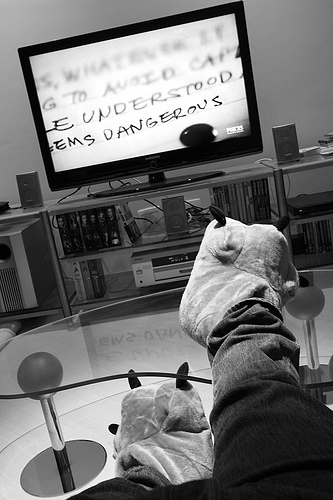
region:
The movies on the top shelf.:
[47, 213, 123, 247]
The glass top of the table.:
[6, 267, 331, 399]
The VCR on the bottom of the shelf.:
[130, 250, 217, 280]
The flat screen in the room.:
[15, 22, 264, 173]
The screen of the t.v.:
[27, 8, 242, 161]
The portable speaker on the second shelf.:
[160, 199, 186, 236]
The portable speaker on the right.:
[270, 120, 301, 162]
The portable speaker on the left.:
[16, 172, 43, 208]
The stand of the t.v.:
[89, 165, 229, 196]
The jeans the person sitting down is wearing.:
[73, 320, 329, 498]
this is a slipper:
[166, 258, 265, 394]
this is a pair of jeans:
[246, 360, 258, 432]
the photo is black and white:
[62, 323, 149, 414]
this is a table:
[129, 318, 196, 369]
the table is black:
[24, 287, 179, 430]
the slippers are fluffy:
[187, 259, 281, 337]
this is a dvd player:
[104, 218, 211, 352]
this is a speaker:
[2, 167, 37, 236]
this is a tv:
[171, 81, 239, 159]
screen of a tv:
[14, 7, 271, 194]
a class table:
[4, 292, 129, 494]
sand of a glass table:
[16, 444, 107, 497]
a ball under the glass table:
[9, 354, 70, 399]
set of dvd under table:
[46, 188, 147, 259]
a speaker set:
[266, 117, 308, 166]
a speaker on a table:
[11, 166, 48, 211]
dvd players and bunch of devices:
[125, 223, 199, 301]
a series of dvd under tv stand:
[191, 170, 280, 228]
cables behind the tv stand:
[180, 195, 217, 228]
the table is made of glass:
[31, 308, 201, 397]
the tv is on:
[22, 36, 265, 168]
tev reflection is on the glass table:
[103, 313, 177, 361]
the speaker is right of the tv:
[270, 118, 297, 159]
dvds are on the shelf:
[67, 213, 139, 245]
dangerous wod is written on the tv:
[32, 55, 251, 152]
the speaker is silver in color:
[6, 226, 53, 311]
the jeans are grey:
[213, 321, 325, 498]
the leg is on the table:
[186, 278, 332, 497]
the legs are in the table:
[193, 218, 301, 338]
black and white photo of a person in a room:
[6, 8, 318, 491]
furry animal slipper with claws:
[105, 363, 208, 477]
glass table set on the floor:
[16, 313, 114, 392]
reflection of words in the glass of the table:
[90, 309, 178, 368]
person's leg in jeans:
[205, 315, 327, 446]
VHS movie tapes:
[53, 204, 134, 247]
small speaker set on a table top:
[6, 167, 45, 209]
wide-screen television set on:
[19, 8, 267, 175]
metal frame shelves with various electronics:
[0, 161, 328, 282]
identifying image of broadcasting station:
[222, 116, 247, 138]